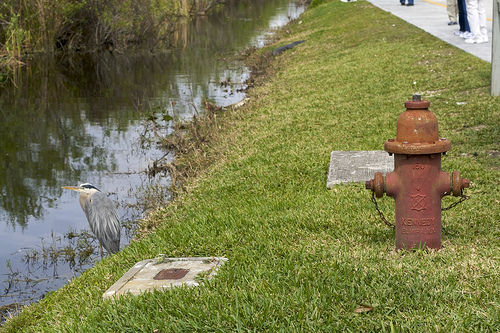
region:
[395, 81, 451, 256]
red fire hydrant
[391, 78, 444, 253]
red fire hydrant in grass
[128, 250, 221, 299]
gray access in grass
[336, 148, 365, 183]
gray block in green grass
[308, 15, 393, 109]
green and brown grass near river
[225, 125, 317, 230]
green and brown grass near river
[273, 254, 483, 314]
green and brown grass near river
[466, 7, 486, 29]
person wearing white pants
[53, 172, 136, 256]
gray and white bird near river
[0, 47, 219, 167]
calm water in river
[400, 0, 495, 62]
people standing on sidwalk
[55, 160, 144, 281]
bird standing in grass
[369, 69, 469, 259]
fire hydrant is red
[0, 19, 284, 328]
grass in in water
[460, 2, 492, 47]
the pants are white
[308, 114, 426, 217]
concrete base in grass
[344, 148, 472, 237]
fire hydrant has chains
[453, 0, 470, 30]
person's pants are black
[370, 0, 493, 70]
sidewalk next to grass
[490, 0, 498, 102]
gray post in grass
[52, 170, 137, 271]
a bird on the riverbank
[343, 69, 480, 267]
an old red fire hydrant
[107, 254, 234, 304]
a cement cover in the ground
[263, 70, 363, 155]
green grass on the river bank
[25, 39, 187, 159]
water in the river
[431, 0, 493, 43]
shoes of people watching the river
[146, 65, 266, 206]
dirt and sticks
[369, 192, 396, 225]
a chain to the fire hydrant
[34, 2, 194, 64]
dead trees on the river bank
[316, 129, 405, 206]
cement stone in the ground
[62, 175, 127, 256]
A grey bird by the pond.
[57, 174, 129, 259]
A bird with a yellow beck standing next to the pond.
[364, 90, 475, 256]
An old hydrant on the grass.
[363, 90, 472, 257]
A faded pink water hydrant.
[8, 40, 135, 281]
Part of the neglected pond.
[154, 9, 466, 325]
Green grass on the ground.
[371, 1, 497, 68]
Sidewalk next to the grass.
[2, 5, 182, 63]
Plantations next to pond.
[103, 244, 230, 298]
Inspection pits next to the pond.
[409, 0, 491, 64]
Feet of people walking along the pavement.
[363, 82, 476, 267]
rusty red fire hydrant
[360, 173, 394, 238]
rusty chain on a fire hydrant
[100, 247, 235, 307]
cement square in the grass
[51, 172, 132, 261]
gray bird by the water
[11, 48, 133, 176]
reflections of trees in the water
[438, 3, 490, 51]
legs of people on the sidewalk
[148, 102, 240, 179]
rugged coastline near a bird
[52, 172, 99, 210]
white head of a bird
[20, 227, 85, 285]
grass growing out of the water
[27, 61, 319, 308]
bird on the grass near the water